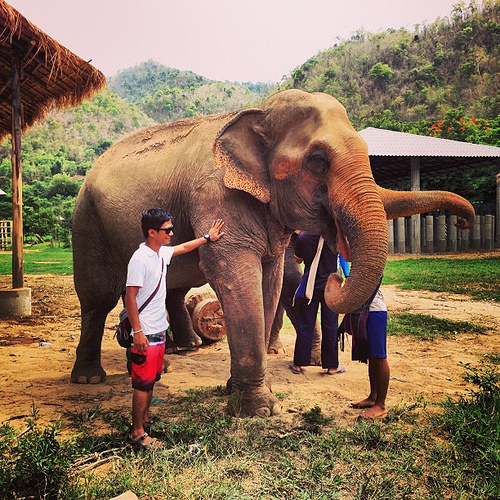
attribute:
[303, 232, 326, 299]
stripe — white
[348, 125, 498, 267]
hut — gray 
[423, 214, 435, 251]
support — wooden 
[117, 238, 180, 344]
shirt — white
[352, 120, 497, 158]
roof — grey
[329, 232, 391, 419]
person — standing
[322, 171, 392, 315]
trunk — elephant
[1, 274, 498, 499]
dirt — yellow dry patch, light brown 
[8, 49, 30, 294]
pole — thick, yellow and brown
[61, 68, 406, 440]
elephant — curved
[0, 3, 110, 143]
roof — grass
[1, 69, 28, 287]
pole — wooden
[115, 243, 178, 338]
shirt — white 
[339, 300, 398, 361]
shorts —  blue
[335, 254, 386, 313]
shirt — white 